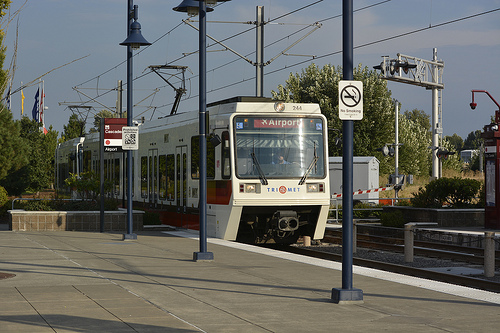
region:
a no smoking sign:
[315, 67, 385, 130]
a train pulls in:
[49, 55, 381, 292]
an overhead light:
[116, 11, 153, 57]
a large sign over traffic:
[380, 42, 473, 98]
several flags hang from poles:
[20, 79, 52, 128]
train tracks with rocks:
[302, 237, 496, 322]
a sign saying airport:
[254, 110, 321, 163]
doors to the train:
[170, 139, 195, 231]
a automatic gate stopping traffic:
[330, 173, 435, 210]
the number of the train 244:
[290, 100, 308, 114]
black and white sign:
[317, 69, 374, 141]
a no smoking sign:
[332, 72, 377, 149]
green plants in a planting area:
[0, 170, 133, 255]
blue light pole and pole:
[97, 17, 164, 251]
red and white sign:
[238, 115, 311, 147]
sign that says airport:
[252, 114, 307, 141]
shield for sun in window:
[242, 124, 330, 161]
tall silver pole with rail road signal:
[342, 42, 458, 194]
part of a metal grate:
[1, 252, 31, 294]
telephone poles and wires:
[0, 16, 325, 124]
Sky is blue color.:
[27, 28, 193, 98]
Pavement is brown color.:
[61, 256, 200, 306]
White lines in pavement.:
[254, 233, 327, 295]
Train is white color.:
[163, 91, 349, 271]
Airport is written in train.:
[256, 115, 331, 140]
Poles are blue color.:
[90, 46, 372, 241]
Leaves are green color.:
[11, 109, 54, 210]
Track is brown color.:
[324, 217, 464, 286]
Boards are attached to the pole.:
[114, 83, 387, 144]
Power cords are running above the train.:
[166, 0, 371, 268]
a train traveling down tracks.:
[92, 43, 347, 243]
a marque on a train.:
[228, 112, 336, 142]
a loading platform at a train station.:
[0, 226, 497, 331]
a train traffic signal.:
[365, 30, 449, 185]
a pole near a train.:
[120, 0, 140, 242]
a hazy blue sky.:
[0, 0, 498, 144]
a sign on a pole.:
[325, 70, 382, 137]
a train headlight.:
[240, 177, 264, 201]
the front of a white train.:
[205, 91, 350, 246]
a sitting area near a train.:
[6, 208, 176, 241]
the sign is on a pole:
[332, 60, 370, 321]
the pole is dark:
[343, 128, 363, 307]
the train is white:
[155, 109, 331, 247]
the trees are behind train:
[256, 48, 423, 201]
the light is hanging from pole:
[125, 5, 143, 242]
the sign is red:
[237, 110, 325, 148]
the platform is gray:
[31, 240, 250, 331]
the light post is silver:
[400, 50, 465, 181]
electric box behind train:
[272, 94, 382, 208]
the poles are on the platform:
[105, 37, 357, 327]